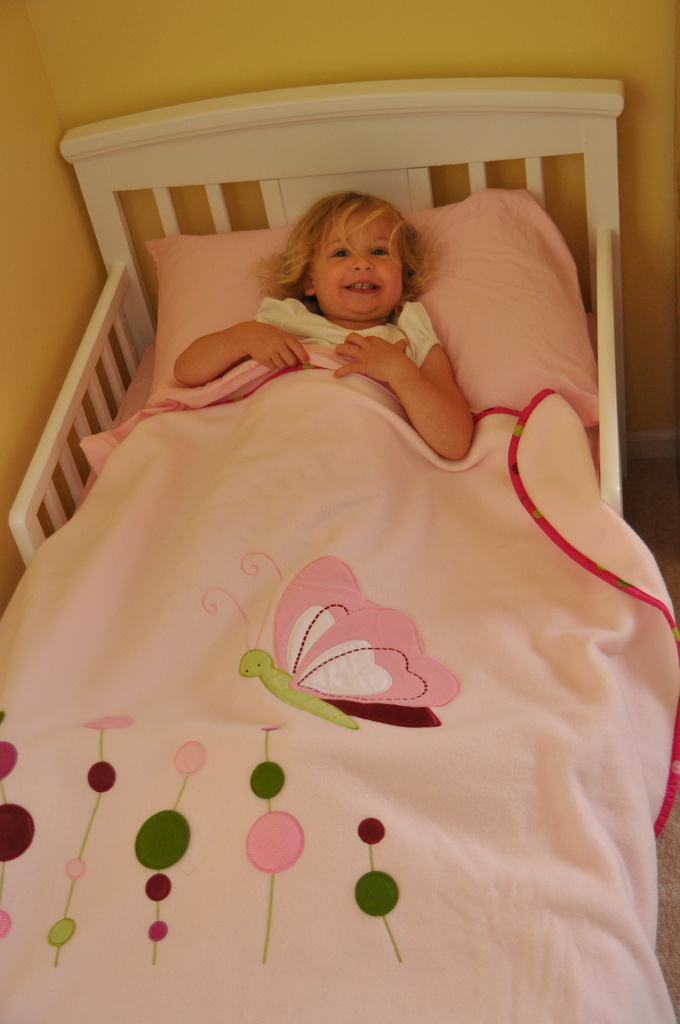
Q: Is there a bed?
A: Yes, there is a bed.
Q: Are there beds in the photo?
A: Yes, there is a bed.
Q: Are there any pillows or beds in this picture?
A: Yes, there is a bed.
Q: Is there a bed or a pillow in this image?
A: Yes, there is a bed.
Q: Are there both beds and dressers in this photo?
A: No, there is a bed but no dressers.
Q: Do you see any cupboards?
A: No, there are no cupboards.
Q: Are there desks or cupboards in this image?
A: No, there are no cupboards or desks.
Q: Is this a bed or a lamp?
A: This is a bed.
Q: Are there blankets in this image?
A: Yes, there is a blanket.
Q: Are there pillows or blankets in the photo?
A: Yes, there is a blanket.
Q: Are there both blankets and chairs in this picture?
A: No, there is a blanket but no chairs.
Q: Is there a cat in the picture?
A: No, there are no cats.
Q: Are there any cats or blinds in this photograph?
A: No, there are no cats or blinds.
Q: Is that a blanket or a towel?
A: That is a blanket.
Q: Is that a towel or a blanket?
A: That is a blanket.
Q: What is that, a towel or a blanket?
A: That is a blanket.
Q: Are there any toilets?
A: No, there are no toilets.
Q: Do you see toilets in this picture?
A: No, there are no toilets.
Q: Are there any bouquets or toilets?
A: No, there are no toilets or bouquets.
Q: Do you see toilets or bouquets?
A: No, there are no toilets or bouquets.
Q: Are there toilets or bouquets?
A: No, there are no toilets or bouquets.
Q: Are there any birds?
A: No, there are no birds.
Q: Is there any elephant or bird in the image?
A: No, there are no birds or elephants.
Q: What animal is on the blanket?
A: The butterfly is on the blanket.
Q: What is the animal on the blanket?
A: The animal is a butterfly.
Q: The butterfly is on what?
A: The butterfly is on the blanket.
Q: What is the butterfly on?
A: The butterfly is on the blanket.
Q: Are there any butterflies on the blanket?
A: Yes, there is a butterfly on the blanket.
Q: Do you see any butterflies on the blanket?
A: Yes, there is a butterfly on the blanket.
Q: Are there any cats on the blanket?
A: No, there is a butterfly on the blanket.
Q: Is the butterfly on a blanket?
A: Yes, the butterfly is on a blanket.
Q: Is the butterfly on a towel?
A: No, the butterfly is on a blanket.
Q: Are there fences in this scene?
A: No, there are no fences.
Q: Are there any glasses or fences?
A: No, there are no fences or glasses.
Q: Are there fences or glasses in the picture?
A: No, there are no fences or glasses.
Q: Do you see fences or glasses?
A: No, there are no fences or glasses.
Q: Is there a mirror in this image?
A: No, there are no mirrors.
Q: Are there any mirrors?
A: No, there are no mirrors.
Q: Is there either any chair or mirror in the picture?
A: No, there are no mirrors or chairs.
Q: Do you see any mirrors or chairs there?
A: No, there are no mirrors or chairs.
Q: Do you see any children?
A: Yes, there is a child.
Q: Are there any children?
A: Yes, there is a child.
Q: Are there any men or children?
A: Yes, there is a child.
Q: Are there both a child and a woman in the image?
A: No, there is a child but no women.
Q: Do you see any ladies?
A: No, there are no ladies.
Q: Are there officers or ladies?
A: No, there are no ladies or officers.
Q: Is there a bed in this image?
A: Yes, there is a bed.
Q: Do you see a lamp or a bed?
A: Yes, there is a bed.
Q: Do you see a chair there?
A: No, there are no chairs.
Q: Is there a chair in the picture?
A: No, there are no chairs.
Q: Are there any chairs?
A: No, there are no chairs.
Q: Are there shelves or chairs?
A: No, there are no chairs or shelves.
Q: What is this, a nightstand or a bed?
A: This is a bed.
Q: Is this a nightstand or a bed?
A: This is a bed.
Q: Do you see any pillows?
A: Yes, there is a pillow.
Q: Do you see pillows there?
A: Yes, there is a pillow.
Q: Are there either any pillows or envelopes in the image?
A: Yes, there is a pillow.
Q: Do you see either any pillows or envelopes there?
A: Yes, there is a pillow.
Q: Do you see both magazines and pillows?
A: No, there is a pillow but no magazines.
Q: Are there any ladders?
A: No, there are no ladders.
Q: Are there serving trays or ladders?
A: No, there are no ladders or serving trays.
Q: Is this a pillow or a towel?
A: This is a pillow.